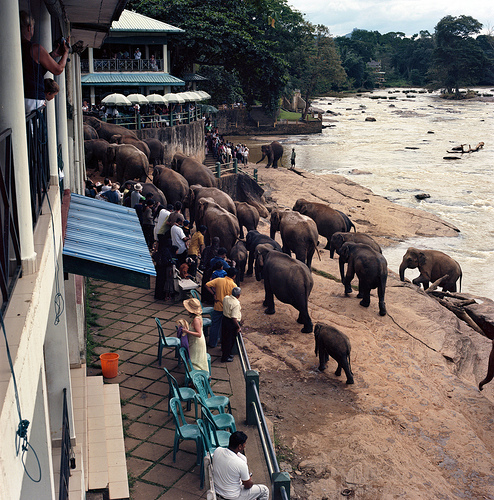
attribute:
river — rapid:
[369, 101, 493, 192]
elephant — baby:
[313, 326, 353, 381]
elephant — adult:
[256, 244, 311, 328]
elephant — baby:
[310, 320, 355, 386]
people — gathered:
[119, 179, 246, 368]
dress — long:
[183, 312, 211, 374]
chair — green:
[149, 319, 180, 362]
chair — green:
[186, 368, 232, 413]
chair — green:
[164, 392, 205, 463]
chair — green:
[194, 416, 227, 459]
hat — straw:
[175, 290, 209, 320]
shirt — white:
[208, 448, 253, 498]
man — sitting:
[196, 422, 287, 498]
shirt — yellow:
[204, 275, 241, 311]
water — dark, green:
[214, 84, 492, 316]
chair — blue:
[164, 394, 206, 459]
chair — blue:
[155, 360, 194, 401]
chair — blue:
[145, 314, 186, 362]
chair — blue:
[183, 365, 238, 413]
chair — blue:
[193, 398, 239, 426]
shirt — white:
[204, 437, 252, 497]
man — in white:
[203, 422, 280, 498]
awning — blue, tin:
[65, 192, 157, 290]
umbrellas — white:
[103, 85, 211, 104]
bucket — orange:
[99, 344, 120, 380]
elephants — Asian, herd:
[93, 114, 468, 399]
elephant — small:
[304, 318, 369, 387]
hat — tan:
[184, 296, 203, 314]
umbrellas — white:
[99, 90, 209, 106]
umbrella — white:
[99, 90, 133, 107]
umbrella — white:
[127, 92, 150, 107]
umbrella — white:
[146, 95, 168, 104]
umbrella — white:
[164, 92, 186, 103]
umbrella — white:
[179, 92, 201, 103]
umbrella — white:
[196, 88, 211, 99]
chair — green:
[192, 416, 215, 452]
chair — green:
[199, 405, 234, 447]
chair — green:
[198, 397, 235, 430]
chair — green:
[160, 366, 199, 418]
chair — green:
[155, 316, 183, 364]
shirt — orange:
[207, 276, 237, 311]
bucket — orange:
[98, 350, 120, 378]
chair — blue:
[193, 418, 216, 479]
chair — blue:
[169, 394, 202, 461]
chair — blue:
[194, 395, 235, 427]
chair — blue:
[163, 366, 196, 411]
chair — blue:
[190, 369, 234, 413]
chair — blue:
[151, 316, 182, 364]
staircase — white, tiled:
[69, 366, 130, 498]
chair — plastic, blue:
[153, 317, 183, 366]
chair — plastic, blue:
[178, 349, 210, 384]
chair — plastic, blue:
[187, 370, 231, 416]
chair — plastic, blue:
[162, 369, 197, 414]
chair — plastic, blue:
[167, 396, 205, 462]